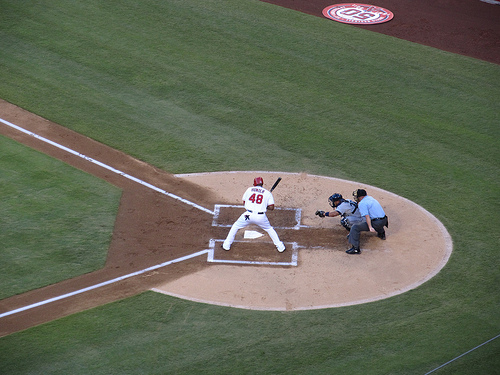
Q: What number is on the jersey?
A: 48.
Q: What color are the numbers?
A: Red.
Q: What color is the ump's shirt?
A: Blue.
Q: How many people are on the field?
A: Three.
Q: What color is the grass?
A: Green.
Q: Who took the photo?
A: Fan.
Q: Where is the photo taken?
A: Field.